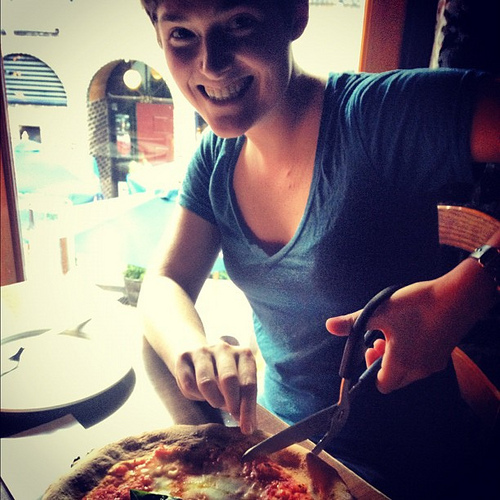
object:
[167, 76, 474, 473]
shirt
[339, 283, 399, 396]
handles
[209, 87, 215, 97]
white tooth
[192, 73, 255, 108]
mouth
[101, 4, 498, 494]
woman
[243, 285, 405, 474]
shears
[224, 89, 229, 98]
tooth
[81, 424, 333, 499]
pizza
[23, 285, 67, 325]
table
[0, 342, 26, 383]
fork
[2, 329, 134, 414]
plate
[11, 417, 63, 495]
counter